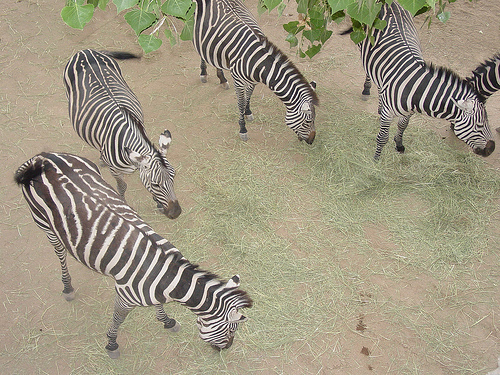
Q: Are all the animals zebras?
A: Yes, all the animals are zebras.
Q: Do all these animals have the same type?
A: Yes, all the animals are zebras.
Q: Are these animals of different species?
A: No, all the animals are zebras.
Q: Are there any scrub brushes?
A: No, there are no scrub brushes.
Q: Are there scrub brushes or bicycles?
A: No, there are no scrub brushes or bicycles.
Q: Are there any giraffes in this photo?
A: No, there are no giraffes.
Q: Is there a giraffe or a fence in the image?
A: No, there are no giraffes or fences.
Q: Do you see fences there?
A: No, there are no fences.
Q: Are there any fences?
A: No, there are no fences.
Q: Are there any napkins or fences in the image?
A: No, there are no fences or napkins.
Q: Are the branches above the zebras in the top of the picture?
A: Yes, the branches are above the zebras.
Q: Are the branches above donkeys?
A: No, the branches are above the zebras.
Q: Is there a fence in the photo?
A: No, there are no fences.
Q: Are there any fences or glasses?
A: No, there are no fences or glasses.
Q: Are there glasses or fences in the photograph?
A: No, there are no fences or glasses.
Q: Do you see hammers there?
A: No, there are no hammers.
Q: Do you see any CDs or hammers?
A: No, there are no hammers or cds.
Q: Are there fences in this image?
A: No, there are no fences.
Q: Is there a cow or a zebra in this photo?
A: Yes, there is a zebra.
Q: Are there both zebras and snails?
A: No, there is a zebra but no snails.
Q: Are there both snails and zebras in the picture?
A: No, there is a zebra but no snails.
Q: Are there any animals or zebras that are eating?
A: Yes, the zebra is eating.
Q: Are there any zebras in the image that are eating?
A: Yes, there is a zebra that is eating.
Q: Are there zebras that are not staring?
A: Yes, there is a zebra that is eating.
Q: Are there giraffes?
A: No, there are no giraffes.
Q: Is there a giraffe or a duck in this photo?
A: No, there are no giraffes or ducks.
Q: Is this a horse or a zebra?
A: This is a zebra.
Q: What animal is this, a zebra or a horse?
A: This is a zebra.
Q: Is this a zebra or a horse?
A: This is a zebra.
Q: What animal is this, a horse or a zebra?
A: This is a zebra.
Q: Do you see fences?
A: No, there are no fences.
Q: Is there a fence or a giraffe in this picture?
A: No, there are no fences or giraffes.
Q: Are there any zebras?
A: Yes, there is a zebra.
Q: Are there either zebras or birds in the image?
A: Yes, there is a zebra.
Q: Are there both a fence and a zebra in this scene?
A: No, there is a zebra but no fences.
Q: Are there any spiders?
A: No, there are no spiders.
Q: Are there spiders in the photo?
A: No, there are no spiders.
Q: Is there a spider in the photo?
A: No, there are no spiders.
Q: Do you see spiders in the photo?
A: No, there are no spiders.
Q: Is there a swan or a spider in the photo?
A: No, there are no spiders or swans.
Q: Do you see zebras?
A: Yes, there is a zebra.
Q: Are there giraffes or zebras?
A: Yes, there is a zebra.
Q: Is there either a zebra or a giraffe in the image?
A: Yes, there is a zebra.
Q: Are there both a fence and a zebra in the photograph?
A: No, there is a zebra but no fences.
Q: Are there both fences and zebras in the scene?
A: No, there is a zebra but no fences.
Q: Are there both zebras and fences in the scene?
A: No, there is a zebra but no fences.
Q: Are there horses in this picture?
A: No, there are no horses.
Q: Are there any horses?
A: No, there are no horses.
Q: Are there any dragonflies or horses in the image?
A: No, there are no horses or dragonflies.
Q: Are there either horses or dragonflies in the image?
A: No, there are no horses or dragonflies.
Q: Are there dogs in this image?
A: No, there are no dogs.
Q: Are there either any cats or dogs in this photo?
A: No, there are no dogs or cats.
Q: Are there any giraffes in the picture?
A: No, there are no giraffes.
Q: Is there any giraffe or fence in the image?
A: No, there are no giraffes or fences.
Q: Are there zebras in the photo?
A: Yes, there are zebras.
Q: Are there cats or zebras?
A: Yes, there are zebras.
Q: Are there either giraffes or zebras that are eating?
A: Yes, the zebras are eating.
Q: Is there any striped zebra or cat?
A: Yes, there are striped zebras.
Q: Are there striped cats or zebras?
A: Yes, there are striped zebras.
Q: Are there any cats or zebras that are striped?
A: Yes, the zebras are striped.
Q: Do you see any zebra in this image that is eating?
A: Yes, there are zebras that are eating.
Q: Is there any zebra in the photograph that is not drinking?
A: Yes, there are zebras that are eating.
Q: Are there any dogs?
A: No, there are no dogs.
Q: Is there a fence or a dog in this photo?
A: No, there are no dogs or fences.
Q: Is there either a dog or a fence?
A: No, there are no dogs or fences.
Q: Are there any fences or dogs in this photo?
A: No, there are no dogs or fences.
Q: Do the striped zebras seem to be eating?
A: Yes, the zebras are eating.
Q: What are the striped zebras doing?
A: The zebras are eating.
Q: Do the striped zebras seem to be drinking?
A: No, the zebras are eating.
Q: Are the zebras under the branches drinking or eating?
A: The zebras are eating.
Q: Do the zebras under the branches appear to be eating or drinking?
A: The zebras are eating.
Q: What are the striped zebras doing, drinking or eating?
A: The zebras are eating.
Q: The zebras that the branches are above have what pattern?
A: The zebras are striped.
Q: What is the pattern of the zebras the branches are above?
A: The zebras are striped.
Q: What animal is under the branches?
A: The zebras are under the branches.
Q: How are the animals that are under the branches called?
A: The animals are zebras.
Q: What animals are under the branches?
A: The animals are zebras.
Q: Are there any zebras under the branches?
A: Yes, there are zebras under the branches.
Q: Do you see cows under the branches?
A: No, there are zebras under the branches.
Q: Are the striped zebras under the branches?
A: Yes, the zebras are under the branches.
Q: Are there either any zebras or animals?
A: Yes, there is a zebra.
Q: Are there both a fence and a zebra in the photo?
A: No, there is a zebra but no fences.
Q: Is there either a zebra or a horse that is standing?
A: Yes, the zebra is standing.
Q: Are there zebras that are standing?
A: Yes, there is a zebra that is standing.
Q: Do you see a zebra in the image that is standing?
A: Yes, there is a zebra that is standing.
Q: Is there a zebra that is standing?
A: Yes, there is a zebra that is standing.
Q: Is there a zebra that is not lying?
A: Yes, there is a zebra that is standing.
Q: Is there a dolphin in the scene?
A: No, there are no dolphins.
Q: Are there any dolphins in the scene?
A: No, there are no dolphins.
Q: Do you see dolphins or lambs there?
A: No, there are no dolphins or lambs.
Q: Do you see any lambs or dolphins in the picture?
A: No, there are no dolphins or lambs.